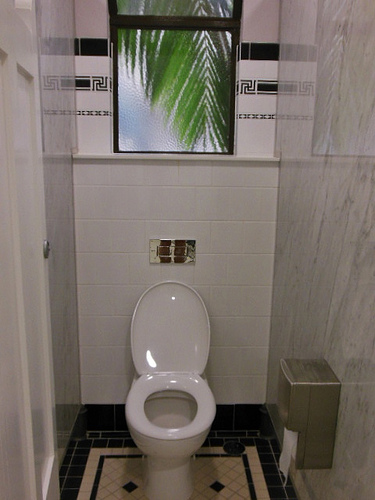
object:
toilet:
[123, 279, 217, 500]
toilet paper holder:
[274, 355, 342, 471]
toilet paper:
[277, 427, 299, 486]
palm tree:
[116, 0, 232, 154]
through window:
[108, 0, 245, 159]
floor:
[60, 430, 296, 500]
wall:
[271, 0, 372, 311]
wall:
[265, 0, 372, 499]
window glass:
[117, 2, 233, 150]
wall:
[37, 35, 313, 159]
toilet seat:
[128, 279, 212, 375]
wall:
[35, 0, 317, 431]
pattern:
[39, 74, 317, 122]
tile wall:
[73, 162, 282, 407]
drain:
[223, 440, 245, 456]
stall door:
[0, 2, 65, 498]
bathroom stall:
[0, 0, 374, 500]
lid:
[129, 279, 211, 377]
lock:
[43, 239, 51, 258]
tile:
[122, 479, 140, 494]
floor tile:
[103, 478, 122, 494]